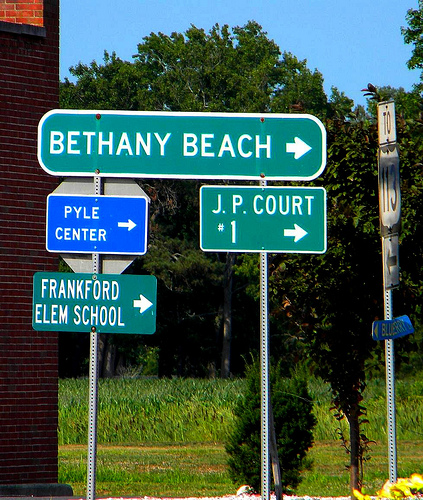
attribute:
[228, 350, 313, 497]
bush — green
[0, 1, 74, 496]
building — brick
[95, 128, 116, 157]
letter — white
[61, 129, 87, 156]
letter — white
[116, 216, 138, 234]
arrow — with an arrow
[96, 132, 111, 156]
letter — white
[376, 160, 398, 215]
113 — a number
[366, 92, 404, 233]
sign — number 113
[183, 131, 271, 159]
beach — a word 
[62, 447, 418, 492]
grass — green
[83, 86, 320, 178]
white sign — green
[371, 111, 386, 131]
ground — green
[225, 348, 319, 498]
green bush — small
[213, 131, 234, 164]
letter — white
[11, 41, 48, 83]
building — with red bricks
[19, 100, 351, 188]
sign — blue and white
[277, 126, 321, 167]
arrow — pointing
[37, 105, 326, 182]
sign — word beach, pointing, with an arrow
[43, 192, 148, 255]
sign — blue, white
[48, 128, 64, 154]
letter — white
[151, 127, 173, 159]
letter — white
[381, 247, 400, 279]
black arrow — to left, pointing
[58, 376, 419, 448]
crops — green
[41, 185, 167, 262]
sign — blue, white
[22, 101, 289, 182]
sign — white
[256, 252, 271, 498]
post — gray